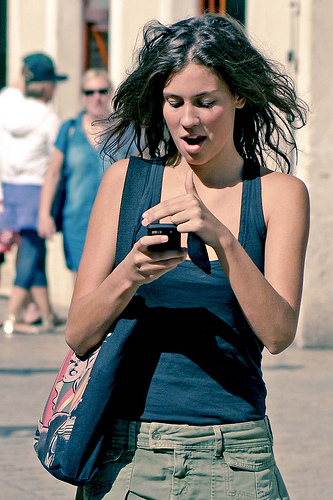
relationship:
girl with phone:
[126, 59, 239, 170] [145, 215, 192, 295]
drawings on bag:
[49, 343, 103, 448] [84, 334, 131, 499]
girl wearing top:
[126, 59, 239, 170] [158, 283, 282, 432]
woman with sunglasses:
[45, 67, 125, 227] [69, 82, 113, 108]